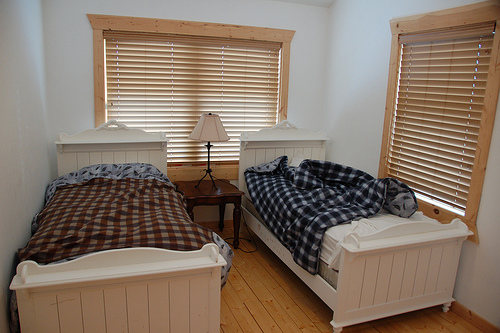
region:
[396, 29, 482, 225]
a window in the bedroom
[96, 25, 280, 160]
blinds on the window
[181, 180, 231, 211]
a small wooden table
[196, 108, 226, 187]
a white lamp on the table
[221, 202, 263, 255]
the cord of the lamp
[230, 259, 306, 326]
hard wood floor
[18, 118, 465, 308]
two white beds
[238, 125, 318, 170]
a white headboard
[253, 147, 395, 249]
a black checkered blanket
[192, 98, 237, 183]
lamp on night stand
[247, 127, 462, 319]
bed on the floor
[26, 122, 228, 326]
bed on the floor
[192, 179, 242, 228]
night stand on the floor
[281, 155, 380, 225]
blanket on the bed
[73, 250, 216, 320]
footboard of the bed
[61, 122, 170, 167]
headboard of the bed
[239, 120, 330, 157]
headboard of the bed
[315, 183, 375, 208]
the bed is unmade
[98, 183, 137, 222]
the bed is made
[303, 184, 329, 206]
the blanket is black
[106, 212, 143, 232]
the blanket is brown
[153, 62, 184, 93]
the blind is closed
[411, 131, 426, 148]
the blind is brown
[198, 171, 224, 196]
the lamp is on the stand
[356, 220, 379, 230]
the sheet in white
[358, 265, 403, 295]
the foot board is white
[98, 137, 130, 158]
the head board is white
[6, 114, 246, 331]
bed next to a wooden table and lamp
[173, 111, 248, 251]
lamp on a wooden table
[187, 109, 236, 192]
lamp with a white shafe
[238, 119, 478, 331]
bed with a dark colored blanket on it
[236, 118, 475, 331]
bed with a white headboard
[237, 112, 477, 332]
unmade bed with a white headboard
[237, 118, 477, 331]
bed with a white wooden frame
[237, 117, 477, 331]
bed with a wooden footboard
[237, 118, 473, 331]
bed with darked colored blanket and white sheet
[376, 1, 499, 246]
wooden window frame and wooden blinds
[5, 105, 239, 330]
single bed in room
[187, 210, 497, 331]
tan hardwood floors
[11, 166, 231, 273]
red and tan checkered blanket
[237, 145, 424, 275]
blue and grey checkered blanket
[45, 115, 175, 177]
white wooden headboard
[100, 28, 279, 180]
wooden blinds on window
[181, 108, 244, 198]
table lamp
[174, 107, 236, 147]
white lampshade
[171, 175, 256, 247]
wooden night table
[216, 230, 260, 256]
black wire on floor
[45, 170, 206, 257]
brown blanket on the bed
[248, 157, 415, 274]
blue blanket on the bed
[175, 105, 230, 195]
lamp on the table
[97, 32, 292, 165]
blinds on the window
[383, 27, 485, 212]
blinds on the window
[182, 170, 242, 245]
table in between two beds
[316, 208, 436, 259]
white sheet on the bed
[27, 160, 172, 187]
gray pillow on the bed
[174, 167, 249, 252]
brown table in the room